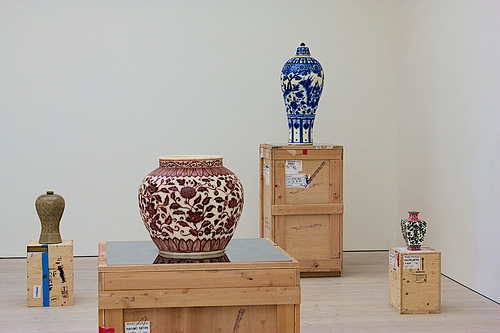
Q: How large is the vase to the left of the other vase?
A: The vase is small.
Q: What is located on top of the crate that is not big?
A: The vase is on top of the crate.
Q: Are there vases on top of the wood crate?
A: Yes, there is a vase on top of the crate.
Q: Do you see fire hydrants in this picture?
A: No, there are no fire hydrants.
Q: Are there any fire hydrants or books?
A: No, there are no fire hydrants or books.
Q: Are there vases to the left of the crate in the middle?
A: Yes, there is a vase to the left of the crate.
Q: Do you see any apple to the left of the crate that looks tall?
A: No, there is a vase to the left of the crate.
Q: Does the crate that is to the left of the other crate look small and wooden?
A: Yes, the crate is small and wooden.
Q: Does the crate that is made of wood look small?
A: Yes, the crate is small.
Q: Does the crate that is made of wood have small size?
A: Yes, the crate is small.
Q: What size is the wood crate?
A: The crate is small.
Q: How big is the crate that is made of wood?
A: The crate is small.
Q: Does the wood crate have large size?
A: No, the crate is small.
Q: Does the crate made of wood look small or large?
A: The crate is small.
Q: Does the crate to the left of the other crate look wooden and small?
A: Yes, the crate is wooden and small.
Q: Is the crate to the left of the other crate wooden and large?
A: No, the crate is wooden but small.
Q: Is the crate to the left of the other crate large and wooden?
A: No, the crate is wooden but small.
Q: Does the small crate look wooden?
A: Yes, the crate is wooden.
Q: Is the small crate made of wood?
A: Yes, the crate is made of wood.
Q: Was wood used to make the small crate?
A: Yes, the crate is made of wood.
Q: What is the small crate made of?
A: The crate is made of wood.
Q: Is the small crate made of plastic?
A: No, the crate is made of wood.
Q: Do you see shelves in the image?
A: No, there are no shelves.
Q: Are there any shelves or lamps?
A: No, there are no shelves or lamps.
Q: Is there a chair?
A: No, there are no chairs.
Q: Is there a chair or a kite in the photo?
A: No, there are no chairs or kites.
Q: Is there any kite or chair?
A: No, there are no chairs or kites.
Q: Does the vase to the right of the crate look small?
A: Yes, the vase is small.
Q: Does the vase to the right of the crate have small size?
A: Yes, the vase is small.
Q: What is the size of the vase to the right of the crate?
A: The vase is small.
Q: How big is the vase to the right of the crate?
A: The vase is small.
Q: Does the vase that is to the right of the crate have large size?
A: No, the vase is small.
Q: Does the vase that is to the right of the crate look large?
A: No, the vase is small.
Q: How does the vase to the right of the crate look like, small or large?
A: The vase is small.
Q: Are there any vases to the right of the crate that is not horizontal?
A: Yes, there is a vase to the right of the crate.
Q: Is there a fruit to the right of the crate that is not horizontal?
A: No, there is a vase to the right of the crate.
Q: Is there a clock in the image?
A: No, there are no clocks.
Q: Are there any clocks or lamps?
A: No, there are no clocks or lamps.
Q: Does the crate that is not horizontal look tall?
A: Yes, the crate is tall.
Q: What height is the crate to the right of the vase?
A: The crate is tall.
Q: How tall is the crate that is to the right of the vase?
A: The crate is tall.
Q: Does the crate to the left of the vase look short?
A: No, the crate is tall.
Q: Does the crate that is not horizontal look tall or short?
A: The crate is tall.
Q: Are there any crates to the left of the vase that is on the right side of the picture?
A: Yes, there is a crate to the left of the vase.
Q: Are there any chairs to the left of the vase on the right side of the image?
A: No, there is a crate to the left of the vase.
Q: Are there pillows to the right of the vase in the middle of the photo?
A: No, there is a crate to the right of the vase.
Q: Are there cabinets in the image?
A: No, there are no cabinets.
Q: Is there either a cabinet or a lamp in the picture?
A: No, there are no cabinets or lamps.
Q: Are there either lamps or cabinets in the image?
A: No, there are no cabinets or lamps.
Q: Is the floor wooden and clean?
A: Yes, the floor is wooden and clean.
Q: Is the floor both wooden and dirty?
A: No, the floor is wooden but clean.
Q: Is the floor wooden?
A: Yes, the floor is wooden.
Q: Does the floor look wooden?
A: Yes, the floor is wooden.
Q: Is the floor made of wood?
A: Yes, the floor is made of wood.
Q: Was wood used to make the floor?
A: Yes, the floor is made of wood.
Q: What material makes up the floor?
A: The floor is made of wood.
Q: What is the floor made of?
A: The floor is made of wood.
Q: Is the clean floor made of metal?
A: No, the floor is made of wood.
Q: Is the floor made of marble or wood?
A: The floor is made of wood.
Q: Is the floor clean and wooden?
A: Yes, the floor is clean and wooden.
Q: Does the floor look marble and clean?
A: No, the floor is clean but wooden.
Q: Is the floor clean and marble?
A: No, the floor is clean but wooden.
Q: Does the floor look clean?
A: Yes, the floor is clean.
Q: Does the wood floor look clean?
A: Yes, the floor is clean.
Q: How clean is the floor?
A: The floor is clean.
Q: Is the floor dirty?
A: No, the floor is clean.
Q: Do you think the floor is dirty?
A: No, the floor is clean.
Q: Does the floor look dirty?
A: No, the floor is clean.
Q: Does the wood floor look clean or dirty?
A: The floor is clean.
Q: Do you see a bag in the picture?
A: No, there are no bags.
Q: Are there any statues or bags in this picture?
A: No, there are no bags or statues.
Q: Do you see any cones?
A: No, there are no cones.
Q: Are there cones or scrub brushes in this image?
A: No, there are no cones or scrub brushes.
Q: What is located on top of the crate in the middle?
A: The vase is on top of the crate.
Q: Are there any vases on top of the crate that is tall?
A: Yes, there is a vase on top of the crate.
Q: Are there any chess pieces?
A: No, there are no chess pieces.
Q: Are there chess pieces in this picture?
A: No, there are no chess pieces.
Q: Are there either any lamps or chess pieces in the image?
A: No, there are no chess pieces or lamps.